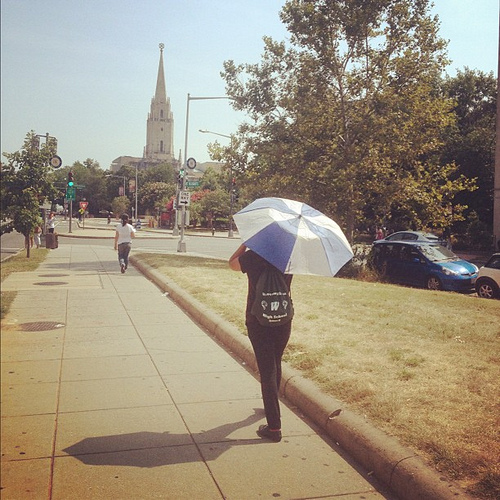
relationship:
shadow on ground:
[45, 401, 290, 473] [1, 210, 500, 499]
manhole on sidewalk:
[11, 316, 67, 339] [2, 239, 404, 500]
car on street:
[362, 231, 480, 302] [89, 220, 500, 303]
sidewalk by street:
[2, 239, 404, 500] [89, 220, 500, 303]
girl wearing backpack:
[226, 225, 304, 446] [247, 267, 296, 337]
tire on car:
[423, 271, 442, 295] [362, 231, 480, 302]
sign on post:
[175, 188, 196, 212] [176, 207, 190, 250]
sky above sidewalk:
[1, 2, 500, 172] [2, 239, 404, 500]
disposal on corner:
[43, 225, 59, 250] [14, 237, 133, 258]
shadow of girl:
[45, 401, 290, 473] [226, 225, 304, 446]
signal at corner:
[67, 166, 75, 195] [14, 237, 133, 258]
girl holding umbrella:
[226, 225, 304, 446] [230, 192, 360, 283]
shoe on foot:
[255, 421, 284, 444] [256, 420, 283, 445]